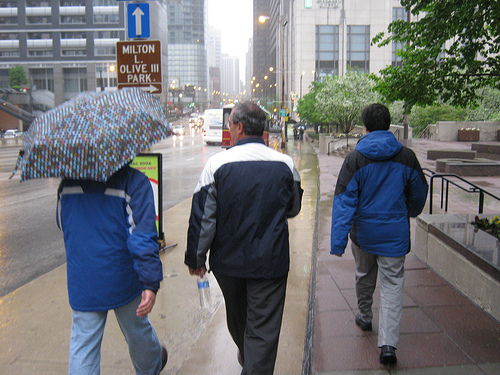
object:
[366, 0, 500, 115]
leaves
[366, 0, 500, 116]
branches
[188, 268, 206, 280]
hand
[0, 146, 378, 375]
ground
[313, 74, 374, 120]
flowers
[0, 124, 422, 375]
sidewalk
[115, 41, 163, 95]
sign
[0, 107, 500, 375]
wet ground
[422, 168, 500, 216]
railing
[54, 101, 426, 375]
people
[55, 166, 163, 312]
jacket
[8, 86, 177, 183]
colored umbrella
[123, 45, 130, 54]
letter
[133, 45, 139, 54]
letter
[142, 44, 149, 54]
letter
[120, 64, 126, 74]
letter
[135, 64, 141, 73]
letter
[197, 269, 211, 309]
bottle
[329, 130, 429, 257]
coat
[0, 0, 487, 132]
buildings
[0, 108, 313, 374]
street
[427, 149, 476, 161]
stone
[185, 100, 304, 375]
man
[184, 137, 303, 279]
jacket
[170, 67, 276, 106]
street lights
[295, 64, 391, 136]
tree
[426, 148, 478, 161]
bench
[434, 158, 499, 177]
bench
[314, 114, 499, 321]
park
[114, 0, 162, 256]
pole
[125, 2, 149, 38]
sign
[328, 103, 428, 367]
man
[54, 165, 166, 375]
man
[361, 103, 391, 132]
hair